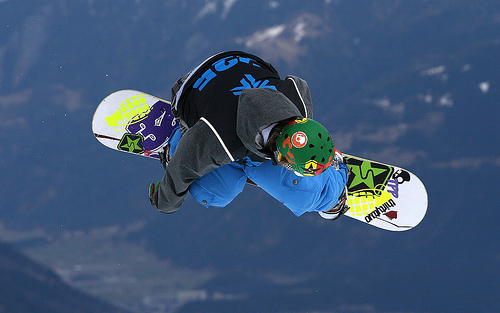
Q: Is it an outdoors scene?
A: Yes, it is outdoors.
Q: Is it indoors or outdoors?
A: It is outdoors.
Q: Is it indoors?
A: No, it is outdoors.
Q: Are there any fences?
A: No, there are no fences.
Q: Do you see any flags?
A: No, there are no flags.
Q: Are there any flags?
A: No, there are no flags.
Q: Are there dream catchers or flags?
A: No, there are no flags or dream catchers.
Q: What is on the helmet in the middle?
A: The sticker is on the helmet.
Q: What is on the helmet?
A: The sticker is on the helmet.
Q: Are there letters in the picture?
A: Yes, there are letters.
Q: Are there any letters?
A: Yes, there are letters.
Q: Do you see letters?
A: Yes, there are letters.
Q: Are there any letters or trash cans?
A: Yes, there are letters.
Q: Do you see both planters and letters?
A: No, there are letters but no planters.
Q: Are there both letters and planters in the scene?
A: No, there are letters but no planters.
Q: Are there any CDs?
A: No, there are no cds.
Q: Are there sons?
A: No, there are no sons.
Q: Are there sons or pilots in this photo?
A: No, there are no sons or pilots.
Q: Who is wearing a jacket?
A: The man is wearing a jacket.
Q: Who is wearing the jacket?
A: The man is wearing a jacket.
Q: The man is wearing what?
A: The man is wearing a jacket.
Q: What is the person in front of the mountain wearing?
A: The man is wearing a jacket.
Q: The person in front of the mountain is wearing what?
A: The man is wearing a jacket.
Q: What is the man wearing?
A: The man is wearing a jacket.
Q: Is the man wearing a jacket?
A: Yes, the man is wearing a jacket.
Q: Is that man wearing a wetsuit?
A: No, the man is wearing a jacket.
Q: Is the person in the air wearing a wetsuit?
A: No, the man is wearing a jacket.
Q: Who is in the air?
A: The man is in the air.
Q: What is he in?
A: The man is in the air.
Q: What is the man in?
A: The man is in the air.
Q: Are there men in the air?
A: Yes, there is a man in the air.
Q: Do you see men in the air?
A: Yes, there is a man in the air.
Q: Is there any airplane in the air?
A: No, there is a man in the air.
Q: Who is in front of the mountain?
A: The man is in front of the mountain.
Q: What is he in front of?
A: The man is in front of the mountain.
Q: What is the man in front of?
A: The man is in front of the mountain.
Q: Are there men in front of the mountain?
A: Yes, there is a man in front of the mountain.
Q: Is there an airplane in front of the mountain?
A: No, there is a man in front of the mountain.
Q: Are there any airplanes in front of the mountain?
A: No, there is a man in front of the mountain.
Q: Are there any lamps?
A: No, there are no lamps.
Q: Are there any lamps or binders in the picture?
A: No, there are no lamps or binders.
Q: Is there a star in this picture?
A: Yes, there is a star.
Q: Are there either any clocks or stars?
A: Yes, there is a star.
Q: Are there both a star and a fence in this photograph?
A: No, there is a star but no fences.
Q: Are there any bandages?
A: No, there are no bandages.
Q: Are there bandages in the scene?
A: No, there are no bandages.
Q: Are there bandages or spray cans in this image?
A: No, there are no bandages or spray cans.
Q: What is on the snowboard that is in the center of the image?
A: The star is on the snowboard.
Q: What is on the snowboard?
A: The star is on the snowboard.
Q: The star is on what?
A: The star is on the snowboard.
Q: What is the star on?
A: The star is on the snowboard.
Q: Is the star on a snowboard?
A: Yes, the star is on a snowboard.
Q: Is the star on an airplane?
A: No, the star is on a snowboard.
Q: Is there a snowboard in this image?
A: Yes, there is a snowboard.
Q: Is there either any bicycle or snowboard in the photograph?
A: Yes, there is a snowboard.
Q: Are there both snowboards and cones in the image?
A: No, there is a snowboard but no cones.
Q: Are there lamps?
A: No, there are no lamps.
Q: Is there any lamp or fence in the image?
A: No, there are no lamps or fences.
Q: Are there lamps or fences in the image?
A: No, there are no lamps or fences.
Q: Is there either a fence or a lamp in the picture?
A: No, there are no lamps or fences.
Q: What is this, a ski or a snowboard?
A: This is a snowboard.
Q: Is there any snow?
A: Yes, there is snow.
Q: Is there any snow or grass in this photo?
A: Yes, there is snow.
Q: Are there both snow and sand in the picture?
A: No, there is snow but no sand.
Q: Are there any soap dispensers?
A: No, there are no soap dispensers.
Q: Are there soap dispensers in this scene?
A: No, there are no soap dispensers.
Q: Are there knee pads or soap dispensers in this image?
A: No, there are no soap dispensers or knee pads.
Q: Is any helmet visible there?
A: Yes, there is a helmet.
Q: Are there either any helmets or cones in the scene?
A: Yes, there is a helmet.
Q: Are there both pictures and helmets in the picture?
A: No, there is a helmet but no pictures.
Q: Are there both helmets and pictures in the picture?
A: No, there is a helmet but no pictures.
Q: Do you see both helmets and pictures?
A: No, there is a helmet but no pictures.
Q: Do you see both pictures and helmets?
A: No, there is a helmet but no pictures.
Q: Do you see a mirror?
A: No, there are no mirrors.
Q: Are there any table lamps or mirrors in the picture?
A: No, there are no mirrors or table lamps.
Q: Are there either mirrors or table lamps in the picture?
A: No, there are no mirrors or table lamps.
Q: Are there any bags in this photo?
A: No, there are no bags.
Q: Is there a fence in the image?
A: No, there are no fences.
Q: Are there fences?
A: No, there are no fences.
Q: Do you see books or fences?
A: No, there are no fences or books.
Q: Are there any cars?
A: No, there are no cars.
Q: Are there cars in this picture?
A: No, there are no cars.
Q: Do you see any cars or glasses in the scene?
A: No, there are no cars or glasses.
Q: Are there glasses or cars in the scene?
A: No, there are no cars or glasses.